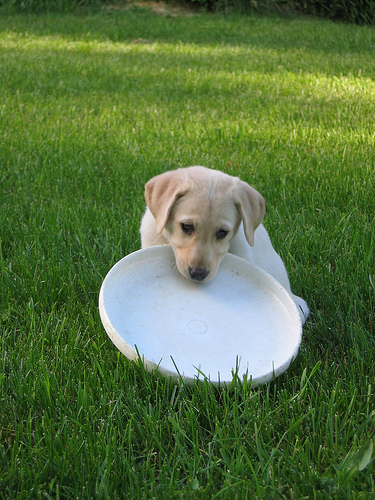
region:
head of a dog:
[136, 155, 279, 288]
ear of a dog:
[136, 162, 192, 238]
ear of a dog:
[232, 176, 273, 245]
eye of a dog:
[173, 210, 211, 245]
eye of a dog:
[208, 220, 231, 245]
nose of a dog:
[173, 247, 228, 280]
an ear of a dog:
[130, 164, 190, 227]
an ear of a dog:
[225, 176, 279, 244]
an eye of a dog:
[173, 205, 208, 245]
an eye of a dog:
[212, 222, 239, 244]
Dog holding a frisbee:
[96, 239, 306, 393]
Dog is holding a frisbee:
[94, 241, 310, 393]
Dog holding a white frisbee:
[97, 240, 307, 393]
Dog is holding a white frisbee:
[92, 241, 304, 394]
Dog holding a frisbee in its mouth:
[90, 239, 308, 394]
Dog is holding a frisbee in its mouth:
[90, 240, 309, 393]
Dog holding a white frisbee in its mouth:
[95, 240, 305, 390]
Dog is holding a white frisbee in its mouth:
[93, 234, 310, 393]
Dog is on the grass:
[87, 154, 323, 398]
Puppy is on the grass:
[93, 161, 322, 401]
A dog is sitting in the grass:
[33, 117, 342, 482]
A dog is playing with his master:
[54, 156, 324, 438]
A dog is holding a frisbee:
[60, 159, 338, 454]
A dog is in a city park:
[75, 153, 339, 458]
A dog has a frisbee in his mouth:
[72, 161, 324, 433]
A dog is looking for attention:
[62, 157, 336, 454]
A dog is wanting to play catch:
[91, 158, 331, 444]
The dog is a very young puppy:
[65, 158, 330, 446]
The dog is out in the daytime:
[93, 162, 337, 423]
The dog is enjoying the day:
[78, 161, 321, 456]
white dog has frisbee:
[133, 144, 302, 334]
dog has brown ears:
[156, 165, 261, 240]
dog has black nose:
[184, 244, 220, 275]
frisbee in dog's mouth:
[116, 248, 276, 386]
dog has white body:
[121, 191, 292, 269]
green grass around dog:
[275, 110, 374, 267]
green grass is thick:
[257, 139, 350, 219]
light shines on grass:
[115, 47, 369, 167]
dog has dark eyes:
[169, 219, 235, 251]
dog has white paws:
[282, 278, 316, 332]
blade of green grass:
[24, 295, 37, 328]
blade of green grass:
[22, 366, 37, 398]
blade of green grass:
[35, 369, 54, 406]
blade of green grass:
[164, 414, 200, 448]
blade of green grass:
[168, 355, 184, 391]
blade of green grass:
[292, 356, 320, 396]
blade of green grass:
[289, 429, 301, 458]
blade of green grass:
[91, 442, 115, 493]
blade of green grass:
[30, 456, 49, 486]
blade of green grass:
[283, 247, 298, 266]